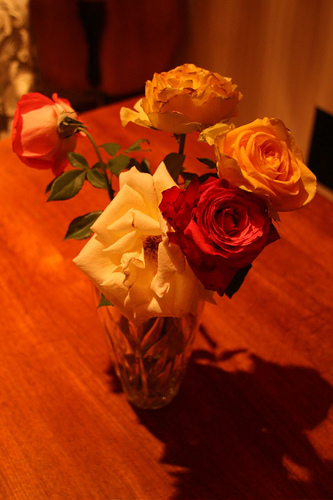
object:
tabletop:
[0, 95, 333, 500]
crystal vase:
[90, 279, 205, 409]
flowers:
[71, 160, 217, 329]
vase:
[90, 279, 205, 410]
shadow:
[102, 347, 333, 500]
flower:
[11, 91, 88, 178]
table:
[0, 91, 332, 500]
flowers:
[197, 117, 318, 222]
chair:
[305, 104, 333, 192]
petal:
[189, 226, 206, 247]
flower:
[158, 175, 281, 298]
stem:
[61, 128, 112, 201]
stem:
[163, 152, 186, 186]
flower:
[119, 62, 242, 132]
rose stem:
[77, 127, 115, 202]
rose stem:
[173, 133, 187, 155]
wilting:
[149, 63, 228, 100]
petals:
[119, 63, 243, 134]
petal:
[154, 86, 191, 112]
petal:
[8, 92, 58, 159]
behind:
[0, 0, 104, 192]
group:
[11, 63, 318, 329]